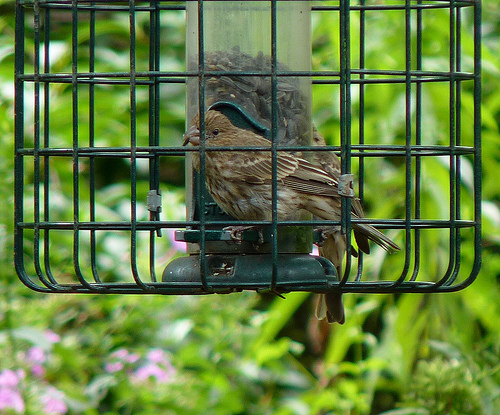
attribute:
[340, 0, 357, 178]
green wire — painted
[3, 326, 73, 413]
flowers — purple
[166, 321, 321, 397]
vegetation — dark green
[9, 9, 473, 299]
cage — metal, green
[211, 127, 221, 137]
eye — very dark, black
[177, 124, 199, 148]
beak — large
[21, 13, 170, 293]
cage — wire